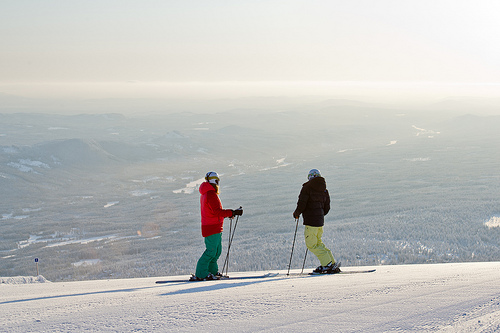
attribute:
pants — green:
[201, 223, 226, 275]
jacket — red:
[199, 182, 233, 235]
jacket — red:
[194, 183, 229, 233]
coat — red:
[175, 174, 247, 241]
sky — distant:
[0, 1, 499, 102]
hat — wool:
[306, 170, 323, 180]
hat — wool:
[205, 170, 220, 184]